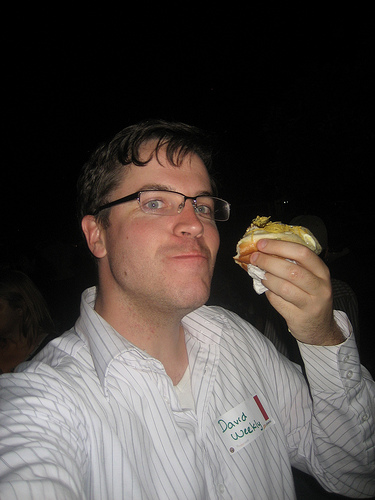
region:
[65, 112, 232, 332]
Head of a person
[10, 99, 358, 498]
This is a person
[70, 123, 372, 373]
a man eating a hotdog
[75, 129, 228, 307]
a man making a funny face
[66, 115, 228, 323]
a man wearing glasses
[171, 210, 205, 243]
the nose of a man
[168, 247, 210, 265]
the mouth of a man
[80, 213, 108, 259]
the ear of a man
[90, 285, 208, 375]
the neck of a man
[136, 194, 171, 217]
the eye of a man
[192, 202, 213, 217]
the eye of a man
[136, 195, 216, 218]
the eyes of a man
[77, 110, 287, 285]
the head of a man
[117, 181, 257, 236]
the eyes of a man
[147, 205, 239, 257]
the nose of a man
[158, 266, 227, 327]
the chin of a man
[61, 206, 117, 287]
the ear of a man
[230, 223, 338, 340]
the hand of a man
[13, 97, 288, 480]
a man wearing a shirt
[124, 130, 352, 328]
a man eating a hot dog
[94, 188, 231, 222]
black framed eye glasses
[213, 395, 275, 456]
name tag on the man's shirt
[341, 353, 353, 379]
white buttons on the sleeve cuff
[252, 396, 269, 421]
red stripe on the name tag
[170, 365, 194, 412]
white under shirt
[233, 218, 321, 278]
food in the man's hand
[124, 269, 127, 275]
brown mole on the man's face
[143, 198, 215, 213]
than man's blue eyes are open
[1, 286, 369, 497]
long sleeve white collared shirt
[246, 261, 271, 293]
white napkin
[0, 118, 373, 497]
Man is in the foreground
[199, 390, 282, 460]
Man has a name tag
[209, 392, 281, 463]
Name tag is written in green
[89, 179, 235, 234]
Man is wearing eyeglasses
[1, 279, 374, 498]
Man is wearing a white dress shirt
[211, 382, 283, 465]
Name tag has a red line on it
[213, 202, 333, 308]
Man is holding food in his hand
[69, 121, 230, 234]
Man has short hair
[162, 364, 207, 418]
Man is wearing a T-Shirt under dress shirt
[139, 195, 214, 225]
Man's eyes are blue in color